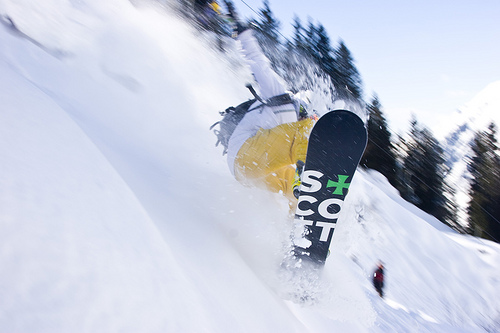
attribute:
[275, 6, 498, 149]
sky — blue, cloudless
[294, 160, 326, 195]
letters — white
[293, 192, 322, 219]
letters — white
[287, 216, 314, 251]
letters — white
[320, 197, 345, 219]
letters — white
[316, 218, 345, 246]
letters — white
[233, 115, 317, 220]
pants — yellow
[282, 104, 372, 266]
snowboard — white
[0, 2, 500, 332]
board — black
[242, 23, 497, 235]
trees — GREEN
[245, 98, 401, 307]
snowboard — black, white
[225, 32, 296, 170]
jacket — white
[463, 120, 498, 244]
trees — green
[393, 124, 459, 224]
trees — green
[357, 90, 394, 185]
trees — green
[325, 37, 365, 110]
trees — green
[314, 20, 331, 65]
trees — green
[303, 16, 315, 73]
trees — green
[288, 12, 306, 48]
trees — green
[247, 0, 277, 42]
trees — green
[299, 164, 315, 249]
lettering — white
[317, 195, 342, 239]
lettering — white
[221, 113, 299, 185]
pants — yellow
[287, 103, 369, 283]
snowboard — black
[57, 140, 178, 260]
snow — white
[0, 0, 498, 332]
mountain — snow-covered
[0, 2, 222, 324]
snow — white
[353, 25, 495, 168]
sky — blue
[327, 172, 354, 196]
cross — green